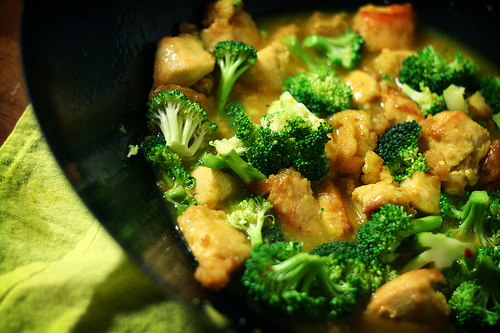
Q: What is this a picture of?
A: Food.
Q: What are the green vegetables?
A: Broccoli.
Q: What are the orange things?
A: Chicken.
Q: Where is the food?
A: In a dish.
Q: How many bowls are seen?
A: 1.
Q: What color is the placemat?
A: Green.